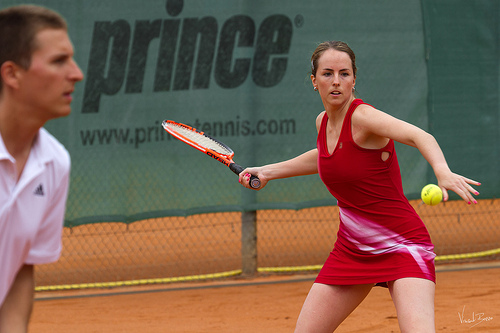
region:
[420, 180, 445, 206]
yellow tennis ball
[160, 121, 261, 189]
red tennis raquet with black grip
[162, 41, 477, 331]
female tennis player wearing red pink and white tennis dress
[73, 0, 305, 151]
ad for prince tennis equipment on green plastic fence windbreak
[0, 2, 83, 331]
man in white polo shirt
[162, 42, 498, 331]
female tennis player prepares to make forehand shot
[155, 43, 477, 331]
right-handed tennis player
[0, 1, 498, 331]
clay tennis court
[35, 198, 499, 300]
chain link fencing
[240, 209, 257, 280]
upright metal pole support for chainlink fence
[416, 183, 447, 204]
Yellow tennis ball in the air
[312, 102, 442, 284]
Woman wearing a red short dress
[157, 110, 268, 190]
Orange tennis rack in the air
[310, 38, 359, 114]
Woman with brown hair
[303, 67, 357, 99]
Woman wearing silver earrings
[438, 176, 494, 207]
Pink painted short nails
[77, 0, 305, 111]
Black letters on a green background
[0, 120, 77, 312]
Man wearing a light pink shirt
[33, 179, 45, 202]
Logo on the right side of a shirt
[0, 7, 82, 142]
Man with short brown hair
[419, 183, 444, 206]
a yellow tennis ball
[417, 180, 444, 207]
a tennis ball in the air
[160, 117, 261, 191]
an orange and black tennis racket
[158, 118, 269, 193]
a tennis racket in the tennis player's hand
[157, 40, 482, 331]
a woman swinging a tennis racket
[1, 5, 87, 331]
a male tennis player on the court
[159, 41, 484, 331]
a female tennis player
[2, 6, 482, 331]
a male and female tennis team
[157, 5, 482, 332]
a woman playing tennis in a tournament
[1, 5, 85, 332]
a male tennis player standing beside a female player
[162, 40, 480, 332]
a woman about to hit a tennis ball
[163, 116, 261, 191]
woman holding an orange tennis racket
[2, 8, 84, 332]
a man standing on a tennis court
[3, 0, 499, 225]
a green tarp on a metal fence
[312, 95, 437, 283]
woman wearing a red dress with pink and white patterns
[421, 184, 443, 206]
a yellow tennis ball in the air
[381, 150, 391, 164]
a hole in woman's dress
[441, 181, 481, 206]
a woman with red nail polish on her fingers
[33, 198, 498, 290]
a metal fence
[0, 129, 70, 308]
man wearing a white polo shirt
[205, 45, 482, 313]
a woman that is playing tennis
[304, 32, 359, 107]
the head of a woman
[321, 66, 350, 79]
the eyes of a woman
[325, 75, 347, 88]
the nose of a woman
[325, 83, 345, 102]
the mouth of a woman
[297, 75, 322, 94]
the ear of a woman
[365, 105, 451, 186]
the left arm of a woman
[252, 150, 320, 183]
the right arm of a woman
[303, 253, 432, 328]
the legs of a woman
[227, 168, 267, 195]
the hand of a woman